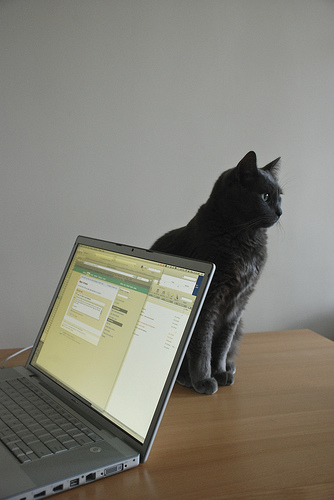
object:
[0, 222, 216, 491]
laptop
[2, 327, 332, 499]
table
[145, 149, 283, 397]
cat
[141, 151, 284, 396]
grey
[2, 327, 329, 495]
brown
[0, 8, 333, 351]
wall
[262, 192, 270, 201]
black and white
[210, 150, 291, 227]
head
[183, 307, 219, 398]
leg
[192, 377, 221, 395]
paw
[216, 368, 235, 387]
paws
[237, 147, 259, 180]
ear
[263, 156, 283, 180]
ears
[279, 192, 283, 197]
eyes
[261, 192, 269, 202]
eye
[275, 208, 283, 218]
nose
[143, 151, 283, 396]
black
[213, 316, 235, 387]
legs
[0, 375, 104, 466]
buttons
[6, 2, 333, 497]
office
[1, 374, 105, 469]
keyboard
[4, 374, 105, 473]
gray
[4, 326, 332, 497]
wood